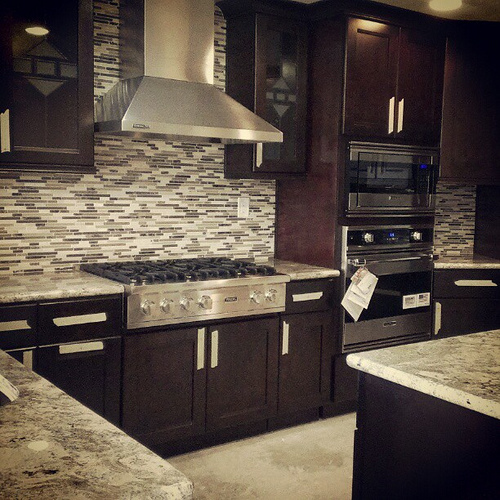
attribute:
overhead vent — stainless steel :
[96, 0, 285, 145]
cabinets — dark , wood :
[3, 274, 337, 467]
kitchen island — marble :
[345, 327, 499, 498]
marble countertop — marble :
[346, 330, 498, 407]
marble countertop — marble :
[436, 252, 498, 272]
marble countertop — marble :
[268, 252, 339, 281]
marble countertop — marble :
[5, 272, 122, 292]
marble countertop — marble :
[4, 370, 184, 498]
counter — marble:
[341, 328, 497, 416]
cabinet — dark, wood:
[342, 10, 444, 137]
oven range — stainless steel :
[81, 257, 291, 327]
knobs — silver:
[139, 298, 157, 316]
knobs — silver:
[159, 298, 178, 317]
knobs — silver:
[180, 296, 197, 313]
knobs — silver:
[199, 294, 215, 310]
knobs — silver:
[249, 290, 264, 306]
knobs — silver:
[267, 290, 279, 303]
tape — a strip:
[387, 95, 395, 135]